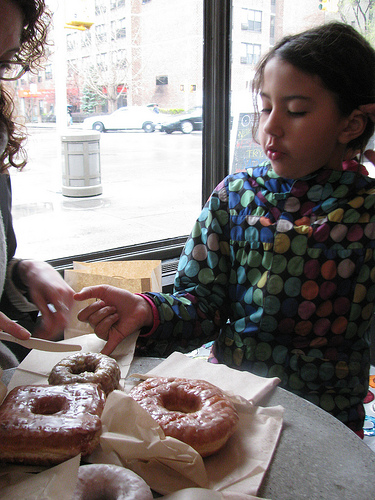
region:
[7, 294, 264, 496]
Four freshly made glazed doughnuts.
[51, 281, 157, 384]
Hand points to one wanted.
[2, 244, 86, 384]
Adult hands plastic knife cuts.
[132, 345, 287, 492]
Brown napkins if needed.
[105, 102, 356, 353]
Girl many colored polka-dot blouse.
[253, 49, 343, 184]
Face shows anticipation eat doughnuts.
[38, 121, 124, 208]
Gray trash can outside sidewalk.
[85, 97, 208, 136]
White and black cars on street.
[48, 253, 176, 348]
Brown paper bag doughnuts bought.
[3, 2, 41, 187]
Adult long curly dark hair.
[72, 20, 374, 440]
the child in front of the donuts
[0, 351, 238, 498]
the donuts on the table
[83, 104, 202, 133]
the cars outside the window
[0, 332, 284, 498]
the napkins on the table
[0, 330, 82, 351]
the plastic knife in the adult's hand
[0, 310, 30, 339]
the finger on the plastic butterknife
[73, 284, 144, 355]
the child's right hand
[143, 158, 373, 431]
the jacket on the child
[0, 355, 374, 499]
the round table under the donuts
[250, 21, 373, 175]
the hair on the child's head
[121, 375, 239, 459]
a large glazed doughnut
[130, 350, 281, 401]
a large white napkin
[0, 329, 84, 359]
part of a white plastic knife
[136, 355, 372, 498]
part of a gray table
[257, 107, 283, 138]
the nose of a girl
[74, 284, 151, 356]
the hand of a girl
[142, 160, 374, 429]
a girl's colorful jacket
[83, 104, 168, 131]
a large white car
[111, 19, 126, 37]
a window of a building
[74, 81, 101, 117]
a small green tree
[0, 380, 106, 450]
A square doughnut on the table.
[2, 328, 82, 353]
A plastic knife being held.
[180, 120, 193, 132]
The right front tire of a black car.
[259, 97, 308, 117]
Pair of eyes on a young girl.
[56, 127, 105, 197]
A public garbage container.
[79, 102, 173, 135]
The non black car on the roadway.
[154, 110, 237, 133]
A black passenger vehicle on the road.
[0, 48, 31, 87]
Part of a pair of eyeglasses being worn.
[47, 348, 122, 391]
The doughnut the girl appears to be touching.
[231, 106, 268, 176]
A partially visible advertising board.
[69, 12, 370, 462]
a girl looking at a doughnut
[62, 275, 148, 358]
her little finger is touching the doughnut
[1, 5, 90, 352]
a woman cutting the doughnut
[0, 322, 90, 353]
her finger is touching the knife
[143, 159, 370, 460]
her dress has coloured dots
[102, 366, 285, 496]
another doughnut on a napkin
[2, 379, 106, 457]
this doughnut has square edges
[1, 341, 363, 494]
the table is round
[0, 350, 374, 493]
the doughnuts are on the table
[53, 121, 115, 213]
a trash can out the window